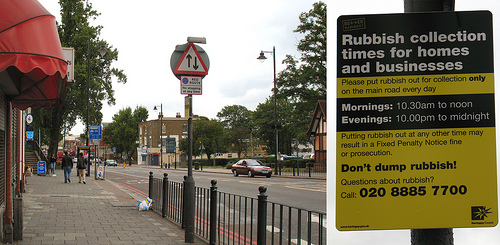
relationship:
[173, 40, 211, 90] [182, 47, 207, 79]
sign has arrows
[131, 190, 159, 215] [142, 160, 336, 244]
bag leaning against fence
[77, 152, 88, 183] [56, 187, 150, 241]
people walking down people sidewalk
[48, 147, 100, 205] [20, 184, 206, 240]
people walking on a sidewalk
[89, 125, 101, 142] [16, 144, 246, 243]
blue sign on a sidewalk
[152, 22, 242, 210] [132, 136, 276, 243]
sign next to fence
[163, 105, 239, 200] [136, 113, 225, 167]
tree near brown building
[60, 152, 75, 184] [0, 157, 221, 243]
people walking on sidewalk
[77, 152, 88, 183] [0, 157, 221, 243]
people walking on sidewalk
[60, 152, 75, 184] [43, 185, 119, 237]
people walking on sidewalk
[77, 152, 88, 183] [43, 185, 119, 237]
people walking on sidewalk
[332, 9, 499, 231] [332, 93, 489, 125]
sign stating times